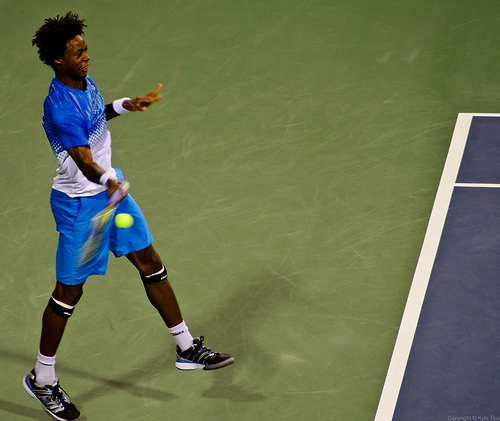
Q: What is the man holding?
A: Racket.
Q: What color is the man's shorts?
A: Blue.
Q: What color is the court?
A: Green.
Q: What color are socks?
A: White.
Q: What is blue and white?
A: Shirt.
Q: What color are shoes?
A: Black.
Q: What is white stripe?
A: Part of tennis court.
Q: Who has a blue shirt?
A: The man.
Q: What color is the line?
A: White.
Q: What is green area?
A: Part of tennis court.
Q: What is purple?
A: Part of the court.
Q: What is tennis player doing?
A: Hitting a ball.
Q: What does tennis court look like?
A: Grey with white borders.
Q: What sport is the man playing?
A: Tennis.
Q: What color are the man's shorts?
A: Blue.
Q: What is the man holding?
A: A tennis racket.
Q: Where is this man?
A: On a tennis court.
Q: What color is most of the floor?
A: Green.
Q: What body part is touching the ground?
A: Right leg.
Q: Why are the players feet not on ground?
A: Player is jumping.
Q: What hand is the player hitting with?
A: Right hand.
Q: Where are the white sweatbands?
A: His wrists.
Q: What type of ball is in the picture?
A: Tennis ball.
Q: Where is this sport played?
A: Tennis court.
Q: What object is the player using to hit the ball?
A: Racquet.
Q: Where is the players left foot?
A: In the air.